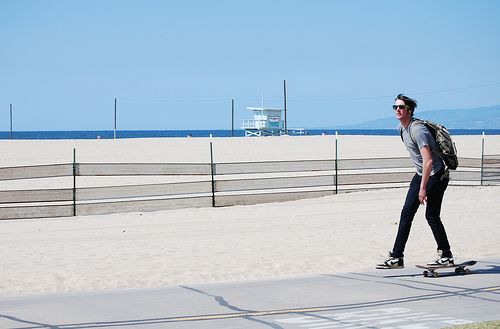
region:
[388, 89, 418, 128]
the head of a man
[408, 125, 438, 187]
the arm of a man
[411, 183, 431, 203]
the hand of a man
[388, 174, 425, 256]
the leg of a man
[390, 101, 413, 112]
a pair of sunglasses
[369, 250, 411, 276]
a black and white shoe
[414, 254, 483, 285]
a surfboard under the man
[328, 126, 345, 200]
a metal fence post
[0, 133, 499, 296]
a white sandy beach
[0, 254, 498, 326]
a gray sidewalk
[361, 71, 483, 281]
Boy is skateboarding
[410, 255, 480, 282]
Skateboard is black and small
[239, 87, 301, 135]
Life guard house on beach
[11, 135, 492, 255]
Sandy beach in background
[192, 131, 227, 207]
Fence post is short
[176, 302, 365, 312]
Yellow line on pavement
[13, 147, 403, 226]
Fence behind boy is long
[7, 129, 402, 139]
Blue water in distance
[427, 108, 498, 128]
Green mountain behind boy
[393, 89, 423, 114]
Wearing sun glasses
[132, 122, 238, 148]
crystal blue ocean in the background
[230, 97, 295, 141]
white life guard stand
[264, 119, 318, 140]
steps leading up to the stand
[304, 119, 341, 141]
objects on the sand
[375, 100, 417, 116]
sunglasses on man's face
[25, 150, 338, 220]
small fence on sidewalk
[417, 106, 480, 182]
gray backpack on man's back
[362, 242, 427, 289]
man's foot levitating on ground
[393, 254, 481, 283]
sneakers on skate board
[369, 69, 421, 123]
man's black hair blowing in the wind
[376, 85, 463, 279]
man on a skateboard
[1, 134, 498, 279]
sand at a beach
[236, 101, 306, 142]
wooden white lifeguard tower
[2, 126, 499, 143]
blue water of the sea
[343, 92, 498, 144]
mountains in the distance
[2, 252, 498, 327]
stretch of paved roadway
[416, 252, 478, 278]
skateboard on the pavement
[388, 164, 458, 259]
man's dark colored jeans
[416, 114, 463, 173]
man's backpack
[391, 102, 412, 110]
sunglasses on a man's face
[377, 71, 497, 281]
guy riding a skateboard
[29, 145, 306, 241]
fence in the sand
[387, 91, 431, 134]
skater wearing sunglasses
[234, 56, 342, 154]
lifeguard stand is white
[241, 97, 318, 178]
lifeguard stand is in the sand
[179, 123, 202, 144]
trash can on the sand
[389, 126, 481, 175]
skater is carrying a backpack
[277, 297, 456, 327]
BIKE written on the sidewalk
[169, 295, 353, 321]
yellow divider on the sidewalk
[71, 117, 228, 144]
ocean is on other side of sand